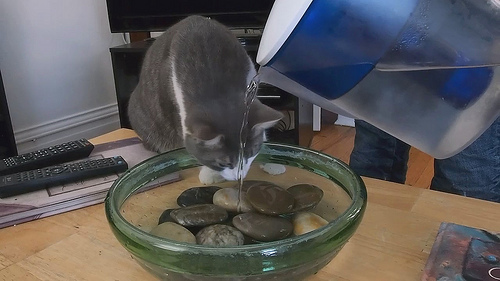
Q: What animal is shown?
A: A cat.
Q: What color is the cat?
A: Grey and white.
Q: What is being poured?
A: Water.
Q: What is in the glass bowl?
A: Rocks.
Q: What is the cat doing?
A: Drinking.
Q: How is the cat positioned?
A: Leaning.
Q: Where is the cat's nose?
A: The bowl.